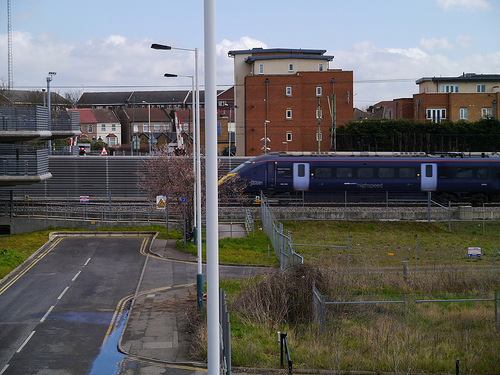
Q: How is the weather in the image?
A: It is cloudy.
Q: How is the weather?
A: It is cloudy.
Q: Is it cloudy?
A: Yes, it is cloudy.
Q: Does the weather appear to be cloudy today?
A: Yes, it is cloudy.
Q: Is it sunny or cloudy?
A: It is cloudy.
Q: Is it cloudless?
A: No, it is cloudy.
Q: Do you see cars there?
A: No, there are no cars.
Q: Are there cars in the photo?
A: No, there are no cars.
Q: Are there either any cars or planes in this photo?
A: No, there are no cars or planes.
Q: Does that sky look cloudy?
A: Yes, the sky is cloudy.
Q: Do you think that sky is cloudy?
A: Yes, the sky is cloudy.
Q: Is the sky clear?
A: No, the sky is cloudy.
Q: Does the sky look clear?
A: No, the sky is cloudy.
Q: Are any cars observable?
A: No, there are no cars.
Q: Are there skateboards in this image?
A: No, there are no skateboards.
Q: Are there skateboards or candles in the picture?
A: No, there are no skateboards or candles.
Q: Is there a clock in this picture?
A: No, there are no clocks.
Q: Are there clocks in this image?
A: No, there are no clocks.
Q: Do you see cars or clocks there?
A: No, there are no clocks or cars.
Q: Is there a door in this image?
A: Yes, there is a door.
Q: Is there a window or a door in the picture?
A: Yes, there is a door.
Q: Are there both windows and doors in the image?
A: Yes, there are both a door and a window.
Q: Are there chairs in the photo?
A: No, there are no chairs.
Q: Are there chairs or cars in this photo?
A: No, there are no chairs or cars.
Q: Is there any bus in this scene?
A: No, there are no buses.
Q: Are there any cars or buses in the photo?
A: No, there are no buses or cars.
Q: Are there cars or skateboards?
A: No, there are no cars or skateboards.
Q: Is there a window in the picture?
A: Yes, there are windows.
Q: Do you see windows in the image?
A: Yes, there are windows.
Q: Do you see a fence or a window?
A: Yes, there are windows.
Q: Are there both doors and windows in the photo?
A: Yes, there are both windows and a door.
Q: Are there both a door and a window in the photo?
A: Yes, there are both a window and a door.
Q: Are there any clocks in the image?
A: No, there are no clocks.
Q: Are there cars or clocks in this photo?
A: No, there are no clocks or cars.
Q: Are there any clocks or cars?
A: No, there are no clocks or cars.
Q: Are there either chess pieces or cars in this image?
A: No, there are no cars or chess pieces.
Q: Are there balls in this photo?
A: No, there are no balls.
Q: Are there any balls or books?
A: No, there are no balls or books.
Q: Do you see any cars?
A: No, there are no cars.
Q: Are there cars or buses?
A: No, there are no cars or buses.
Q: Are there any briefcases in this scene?
A: No, there are no briefcases.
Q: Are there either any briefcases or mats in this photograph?
A: No, there are no briefcases or mats.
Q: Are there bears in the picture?
A: No, there are no bears.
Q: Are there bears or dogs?
A: No, there are no bears or dogs.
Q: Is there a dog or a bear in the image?
A: No, there are no bears or dogs.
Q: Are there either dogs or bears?
A: No, there are no bears or dogs.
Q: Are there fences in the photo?
A: Yes, there is a fence.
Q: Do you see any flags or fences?
A: Yes, there is a fence.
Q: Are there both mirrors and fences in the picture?
A: No, there is a fence but no mirrors.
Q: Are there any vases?
A: No, there are no vases.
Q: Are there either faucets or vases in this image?
A: No, there are no vases or faucets.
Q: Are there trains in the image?
A: Yes, there is a train.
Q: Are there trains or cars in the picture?
A: Yes, there is a train.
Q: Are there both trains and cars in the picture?
A: No, there is a train but no cars.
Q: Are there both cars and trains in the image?
A: No, there is a train but no cars.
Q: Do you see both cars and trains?
A: No, there is a train but no cars.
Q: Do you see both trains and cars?
A: No, there is a train but no cars.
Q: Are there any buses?
A: No, there are no buses.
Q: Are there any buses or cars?
A: No, there are no buses or cars.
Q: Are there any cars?
A: No, there are no cars.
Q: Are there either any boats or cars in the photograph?
A: No, there are no cars or boats.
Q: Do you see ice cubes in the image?
A: No, there are no ice cubes.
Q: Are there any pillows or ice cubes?
A: No, there are no ice cubes or pillows.